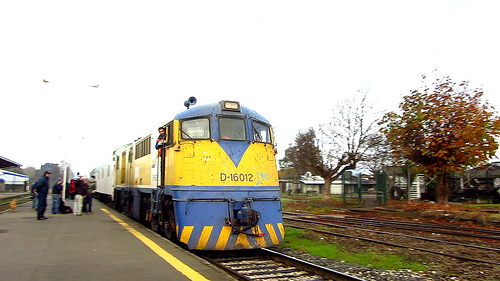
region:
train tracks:
[213, 248, 347, 280]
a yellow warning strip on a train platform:
[99, 206, 185, 280]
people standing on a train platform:
[28, 161, 103, 218]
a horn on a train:
[174, 92, 205, 111]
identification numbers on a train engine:
[212, 167, 265, 184]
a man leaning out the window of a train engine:
[147, 118, 182, 154]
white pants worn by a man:
[68, 193, 89, 220]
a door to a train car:
[113, 146, 133, 187]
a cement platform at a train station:
[19, 221, 130, 271]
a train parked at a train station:
[78, 96, 308, 256]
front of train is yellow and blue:
[174, 92, 291, 254]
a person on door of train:
[150, 120, 173, 187]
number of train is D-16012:
[213, 165, 258, 187]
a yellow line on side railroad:
[128, 224, 259, 279]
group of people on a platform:
[19, 157, 109, 224]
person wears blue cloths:
[30, 167, 55, 224]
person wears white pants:
[70, 173, 87, 216]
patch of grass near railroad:
[281, 227, 396, 279]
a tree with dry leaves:
[374, 67, 498, 209]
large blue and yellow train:
[87, 101, 285, 259]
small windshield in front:
[181, 112, 276, 142]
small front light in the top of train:
[221, 99, 241, 112]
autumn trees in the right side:
[285, 84, 487, 194]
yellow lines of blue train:
[179, 219, 290, 246]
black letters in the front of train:
[219, 170, 257, 184]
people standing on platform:
[31, 171, 91, 218]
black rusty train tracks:
[223, 245, 359, 279]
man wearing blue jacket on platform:
[32, 169, 53, 220]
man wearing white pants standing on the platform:
[71, 178, 85, 211]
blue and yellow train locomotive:
[112, 95, 286, 250]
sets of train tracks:
[198, 211, 498, 280]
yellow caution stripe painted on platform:
[100, 206, 212, 277]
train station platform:
[1, 192, 241, 277]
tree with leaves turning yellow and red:
[372, 75, 494, 195]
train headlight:
[218, 98, 239, 109]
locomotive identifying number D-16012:
[218, 173, 255, 181]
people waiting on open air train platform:
[28, 173, 95, 218]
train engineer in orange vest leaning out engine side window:
[155, 125, 167, 155]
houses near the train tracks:
[280, 161, 498, 199]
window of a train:
[182, 118, 217, 143]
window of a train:
[210, 116, 257, 144]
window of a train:
[252, 122, 276, 147]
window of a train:
[143, 136, 157, 158]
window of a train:
[133, 138, 143, 159]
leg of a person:
[32, 189, 50, 217]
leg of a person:
[43, 193, 68, 208]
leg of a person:
[67, 198, 87, 215]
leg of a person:
[85, 195, 102, 207]